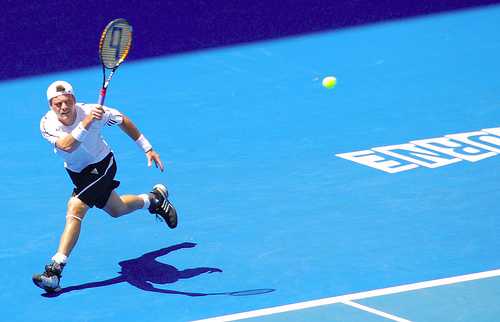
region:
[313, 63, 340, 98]
this is a tennis ball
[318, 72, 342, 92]
the ball is green in color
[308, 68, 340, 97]
the ball is small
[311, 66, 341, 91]
the ball is in the air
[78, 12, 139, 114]
this is a racket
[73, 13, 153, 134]
the man is holding a racket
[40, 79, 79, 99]
this is a cap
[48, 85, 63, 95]
the cap is white in color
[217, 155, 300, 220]
this is the ground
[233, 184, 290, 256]
the ground is blue in color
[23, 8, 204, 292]
man playing tennis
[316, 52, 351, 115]
tennis ball flying through the air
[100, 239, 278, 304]
shadow on the tennis court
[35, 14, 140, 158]
man holding a tennis racquet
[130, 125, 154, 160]
sweat band on the man's wrist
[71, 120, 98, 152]
sweat band on the man's wrist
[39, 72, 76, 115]
cap on the man's head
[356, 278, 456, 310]
white line on the tennis court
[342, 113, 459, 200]
letters on the tennis court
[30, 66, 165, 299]
man wearing black shorts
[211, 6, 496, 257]
yellow tennis ball over court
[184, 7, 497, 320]
blue court with white lines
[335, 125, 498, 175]
white squares with blue letters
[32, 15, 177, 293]
player running on court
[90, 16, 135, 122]
tennis racket in hand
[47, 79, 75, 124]
backwards cap on head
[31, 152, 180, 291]
black shorts on body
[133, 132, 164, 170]
white band on wrist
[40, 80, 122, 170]
white short sleeved shirt on man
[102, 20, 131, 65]
letter on white strings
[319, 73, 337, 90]
yellow tennis ball flying through the air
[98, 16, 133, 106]
Prince wooden tennis racket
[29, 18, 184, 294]
male tennis player just finishing his forehand shot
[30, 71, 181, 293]
male tennis player wearing black shorts, white shirt and white cap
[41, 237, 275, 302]
shadow of tennis player cast on the court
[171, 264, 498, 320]
white striped boundary lines of tennis court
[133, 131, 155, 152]
white sport wrist band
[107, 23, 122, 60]
tennis racket logo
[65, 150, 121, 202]
black tennis shorts with white side stripe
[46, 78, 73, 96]
white baseball style cap worn backward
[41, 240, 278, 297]
man's shadow on the tennis court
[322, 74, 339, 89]
tennis ball in mid-air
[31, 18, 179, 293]
man holding a tennis racket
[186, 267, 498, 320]
white lines on the tennis court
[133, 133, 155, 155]
white wristband on wrist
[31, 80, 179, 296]
young man wearing white shirt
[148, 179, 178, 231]
right foot in air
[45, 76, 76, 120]
white cap on head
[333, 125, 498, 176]
letters on the tennis court